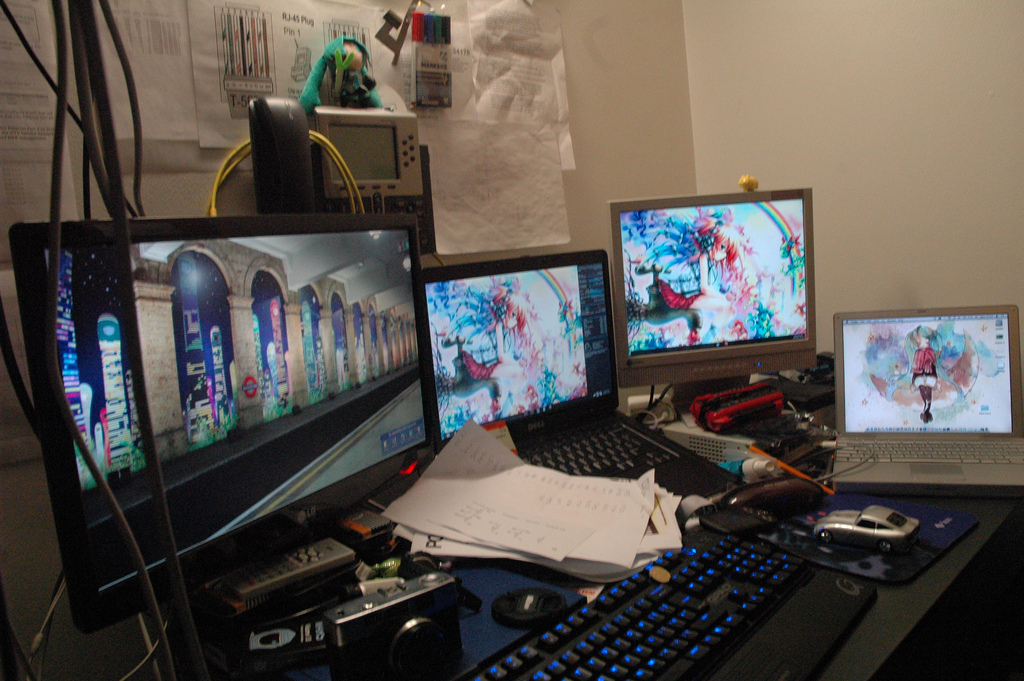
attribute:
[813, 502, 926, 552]
toy — silver , sports car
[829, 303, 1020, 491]
laptop — silver 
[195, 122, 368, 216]
cord — yellow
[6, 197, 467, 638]
monitor — large , black 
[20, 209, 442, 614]
monitor — black , large 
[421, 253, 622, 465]
monitor — black 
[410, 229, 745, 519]
laptop — black 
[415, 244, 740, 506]
laptop — black 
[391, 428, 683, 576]
papers — stack  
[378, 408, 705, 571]
papers — stack  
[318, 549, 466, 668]
camera — black , digital 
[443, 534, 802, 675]
keyboard — lighted 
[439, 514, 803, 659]
keyboard — lighted 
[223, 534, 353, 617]
remote control — gray 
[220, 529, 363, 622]
remote control — gray 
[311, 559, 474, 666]
camera — black , digital 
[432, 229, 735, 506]
laptop — black 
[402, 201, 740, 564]
laptop — black 